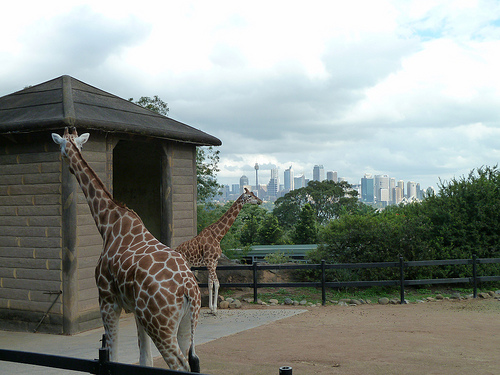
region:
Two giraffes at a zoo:
[54, 113, 265, 361]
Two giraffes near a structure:
[38, 119, 272, 348]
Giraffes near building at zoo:
[18, 52, 213, 297]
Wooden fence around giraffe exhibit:
[271, 257, 485, 304]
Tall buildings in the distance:
[263, 142, 420, 219]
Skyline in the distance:
[264, 152, 447, 212]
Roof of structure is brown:
[14, 60, 219, 153]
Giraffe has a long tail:
[180, 281, 206, 368]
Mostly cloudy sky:
[180, 4, 452, 181]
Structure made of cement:
[5, 154, 93, 313]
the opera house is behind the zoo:
[388, 191, 425, 216]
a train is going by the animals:
[191, 204, 366, 280]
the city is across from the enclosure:
[208, 155, 440, 215]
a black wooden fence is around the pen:
[188, 254, 498, 304]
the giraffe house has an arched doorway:
[1, 72, 228, 348]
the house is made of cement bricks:
[6, 128, 204, 342]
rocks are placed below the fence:
[199, 288, 498, 310]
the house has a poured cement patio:
[1, 299, 312, 370]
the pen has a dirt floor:
[156, 305, 498, 372]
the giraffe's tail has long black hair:
[185, 293, 200, 374]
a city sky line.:
[198, 140, 454, 219]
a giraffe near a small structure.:
[41, 123, 218, 374]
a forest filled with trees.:
[198, 145, 498, 302]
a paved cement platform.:
[1, 283, 341, 363]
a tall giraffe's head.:
[226, 190, 283, 216]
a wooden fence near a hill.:
[197, 255, 498, 305]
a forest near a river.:
[201, 180, 371, 248]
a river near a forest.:
[234, 242, 331, 260]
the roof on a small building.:
[1, 77, 230, 144]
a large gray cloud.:
[314, 28, 497, 160]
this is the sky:
[143, 15, 444, 65]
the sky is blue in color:
[77, 33, 102, 56]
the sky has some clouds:
[242, 31, 317, 107]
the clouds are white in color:
[217, 18, 316, 96]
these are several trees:
[287, 175, 484, 268]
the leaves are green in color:
[335, 215, 407, 245]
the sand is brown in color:
[310, 328, 420, 360]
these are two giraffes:
[46, 123, 269, 364]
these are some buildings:
[271, 170, 418, 202]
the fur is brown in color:
[113, 228, 131, 262]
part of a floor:
[334, 309, 355, 331]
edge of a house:
[53, 216, 82, 256]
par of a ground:
[381, 300, 420, 360]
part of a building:
[366, 161, 388, 185]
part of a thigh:
[145, 259, 179, 309]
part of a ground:
[376, 317, 425, 367]